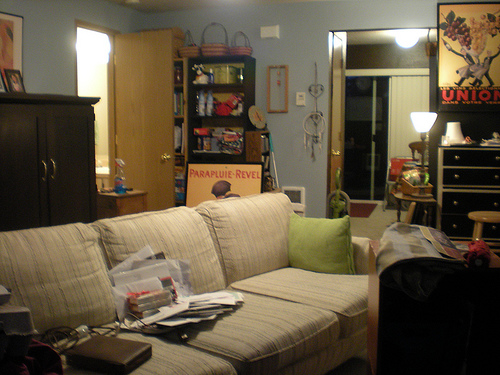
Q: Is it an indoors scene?
A: Yes, it is indoors.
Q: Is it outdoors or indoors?
A: It is indoors.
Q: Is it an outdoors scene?
A: No, it is indoors.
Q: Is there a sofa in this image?
A: Yes, there is a sofa.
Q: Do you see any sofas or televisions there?
A: Yes, there is a sofa.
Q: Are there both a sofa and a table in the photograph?
A: Yes, there are both a sofa and a table.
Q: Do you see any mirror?
A: No, there are no mirrors.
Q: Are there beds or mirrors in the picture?
A: No, there are no mirrors or beds.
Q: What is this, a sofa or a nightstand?
A: This is a sofa.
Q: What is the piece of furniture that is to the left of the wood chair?
A: The piece of furniture is a sofa.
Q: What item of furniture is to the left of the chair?
A: The piece of furniture is a sofa.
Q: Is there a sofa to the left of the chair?
A: Yes, there is a sofa to the left of the chair.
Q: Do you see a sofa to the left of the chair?
A: Yes, there is a sofa to the left of the chair.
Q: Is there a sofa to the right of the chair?
A: No, the sofa is to the left of the chair.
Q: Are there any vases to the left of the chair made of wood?
A: No, there is a sofa to the left of the chair.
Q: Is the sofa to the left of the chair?
A: Yes, the sofa is to the left of the chair.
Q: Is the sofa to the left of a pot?
A: No, the sofa is to the left of the chair.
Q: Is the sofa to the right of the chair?
A: No, the sofa is to the left of the chair.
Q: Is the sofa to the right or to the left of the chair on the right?
A: The sofa is to the left of the chair.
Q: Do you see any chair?
A: Yes, there is a chair.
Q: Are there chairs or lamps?
A: Yes, there is a chair.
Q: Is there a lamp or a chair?
A: Yes, there is a chair.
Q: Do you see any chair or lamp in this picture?
A: Yes, there is a chair.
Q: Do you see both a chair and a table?
A: Yes, there are both a chair and a table.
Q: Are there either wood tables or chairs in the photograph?
A: Yes, there is a wood chair.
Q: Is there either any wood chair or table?
A: Yes, there is a wood chair.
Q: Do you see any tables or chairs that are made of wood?
A: Yes, the chair is made of wood.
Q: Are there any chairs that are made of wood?
A: Yes, there is a chair that is made of wood.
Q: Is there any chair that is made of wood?
A: Yes, there is a chair that is made of wood.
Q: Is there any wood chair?
A: Yes, there is a chair that is made of wood.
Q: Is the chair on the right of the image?
A: Yes, the chair is on the right of the image.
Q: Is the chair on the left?
A: No, the chair is on the right of the image.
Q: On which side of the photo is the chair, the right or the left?
A: The chair is on the right of the image.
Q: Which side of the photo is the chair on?
A: The chair is on the right of the image.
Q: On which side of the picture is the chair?
A: The chair is on the right of the image.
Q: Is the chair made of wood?
A: Yes, the chair is made of wood.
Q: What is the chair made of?
A: The chair is made of wood.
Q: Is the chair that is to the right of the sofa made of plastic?
A: No, the chair is made of wood.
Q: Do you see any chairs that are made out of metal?
A: No, there is a chair but it is made of wood.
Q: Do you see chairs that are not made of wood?
A: No, there is a chair but it is made of wood.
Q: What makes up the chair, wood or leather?
A: The chair is made of wood.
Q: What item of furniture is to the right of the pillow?
A: The piece of furniture is a chair.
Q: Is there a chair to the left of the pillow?
A: No, the chair is to the right of the pillow.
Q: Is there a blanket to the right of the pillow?
A: No, there is a chair to the right of the pillow.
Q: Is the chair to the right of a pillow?
A: Yes, the chair is to the right of a pillow.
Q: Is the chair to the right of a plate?
A: No, the chair is to the right of a pillow.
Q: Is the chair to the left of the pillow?
A: No, the chair is to the right of the pillow.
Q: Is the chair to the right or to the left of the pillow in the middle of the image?
A: The chair is to the right of the pillow.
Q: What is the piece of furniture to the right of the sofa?
A: The piece of furniture is a chair.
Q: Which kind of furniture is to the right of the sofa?
A: The piece of furniture is a chair.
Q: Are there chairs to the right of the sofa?
A: Yes, there is a chair to the right of the sofa.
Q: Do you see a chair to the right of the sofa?
A: Yes, there is a chair to the right of the sofa.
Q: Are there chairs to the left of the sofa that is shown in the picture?
A: No, the chair is to the right of the sofa.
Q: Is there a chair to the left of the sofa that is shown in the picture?
A: No, the chair is to the right of the sofa.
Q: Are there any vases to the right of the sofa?
A: No, there is a chair to the right of the sofa.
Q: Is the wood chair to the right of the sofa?
A: Yes, the chair is to the right of the sofa.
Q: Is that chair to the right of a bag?
A: No, the chair is to the right of the sofa.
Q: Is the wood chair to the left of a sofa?
A: No, the chair is to the right of a sofa.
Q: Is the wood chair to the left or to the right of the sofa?
A: The chair is to the right of the sofa.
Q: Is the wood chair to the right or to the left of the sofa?
A: The chair is to the right of the sofa.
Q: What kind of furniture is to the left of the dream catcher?
A: The piece of furniture is a bookshelf.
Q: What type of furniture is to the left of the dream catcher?
A: The piece of furniture is a bookshelf.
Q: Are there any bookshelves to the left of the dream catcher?
A: Yes, there is a bookshelf to the left of the dream catcher.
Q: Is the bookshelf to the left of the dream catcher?
A: Yes, the bookshelf is to the left of the dream catcher.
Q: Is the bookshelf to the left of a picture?
A: No, the bookshelf is to the left of the dream catcher.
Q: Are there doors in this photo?
A: Yes, there is a door.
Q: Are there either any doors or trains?
A: Yes, there is a door.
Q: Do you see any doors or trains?
A: Yes, there is a door.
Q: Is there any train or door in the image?
A: Yes, there is a door.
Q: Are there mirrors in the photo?
A: No, there are no mirrors.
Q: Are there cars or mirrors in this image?
A: No, there are no mirrors or cars.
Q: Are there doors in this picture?
A: Yes, there are doors.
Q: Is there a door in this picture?
A: Yes, there are doors.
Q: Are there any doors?
A: Yes, there are doors.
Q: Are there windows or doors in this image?
A: Yes, there are doors.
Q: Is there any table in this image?
A: Yes, there is a table.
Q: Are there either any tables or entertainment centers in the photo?
A: Yes, there is a table.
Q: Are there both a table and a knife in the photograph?
A: No, there is a table but no knives.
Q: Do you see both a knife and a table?
A: No, there is a table but no knives.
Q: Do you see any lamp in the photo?
A: Yes, there is a lamp.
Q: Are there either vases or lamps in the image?
A: Yes, there is a lamp.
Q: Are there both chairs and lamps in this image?
A: Yes, there are both a lamp and a chair.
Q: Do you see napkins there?
A: No, there are no napkins.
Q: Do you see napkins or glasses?
A: No, there are no napkins or glasses.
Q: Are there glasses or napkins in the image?
A: No, there are no napkins or glasses.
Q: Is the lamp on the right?
A: Yes, the lamp is on the right of the image.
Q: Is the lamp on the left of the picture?
A: No, the lamp is on the right of the image.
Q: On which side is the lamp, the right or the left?
A: The lamp is on the right of the image.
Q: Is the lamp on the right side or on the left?
A: The lamp is on the right of the image.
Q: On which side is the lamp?
A: The lamp is on the right of the image.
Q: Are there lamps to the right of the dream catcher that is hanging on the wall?
A: Yes, there is a lamp to the right of the dream catcher.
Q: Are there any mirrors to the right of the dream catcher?
A: No, there is a lamp to the right of the dream catcher.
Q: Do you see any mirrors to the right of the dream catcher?
A: No, there is a lamp to the right of the dream catcher.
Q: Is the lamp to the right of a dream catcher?
A: Yes, the lamp is to the right of a dream catcher.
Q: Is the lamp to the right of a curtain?
A: No, the lamp is to the right of a dream catcher.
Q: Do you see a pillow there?
A: Yes, there is a pillow.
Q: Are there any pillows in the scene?
A: Yes, there is a pillow.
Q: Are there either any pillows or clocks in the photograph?
A: Yes, there is a pillow.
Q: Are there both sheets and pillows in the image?
A: No, there is a pillow but no sheets.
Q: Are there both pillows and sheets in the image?
A: No, there is a pillow but no sheets.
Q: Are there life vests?
A: No, there are no life vests.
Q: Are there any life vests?
A: No, there are no life vests.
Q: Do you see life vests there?
A: No, there are no life vests.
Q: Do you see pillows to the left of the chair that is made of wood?
A: Yes, there is a pillow to the left of the chair.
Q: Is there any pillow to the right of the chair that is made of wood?
A: No, the pillow is to the left of the chair.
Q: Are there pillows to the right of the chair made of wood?
A: No, the pillow is to the left of the chair.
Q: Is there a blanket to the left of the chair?
A: No, there is a pillow to the left of the chair.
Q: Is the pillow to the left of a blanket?
A: No, the pillow is to the left of the chair.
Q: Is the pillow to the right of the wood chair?
A: No, the pillow is to the left of the chair.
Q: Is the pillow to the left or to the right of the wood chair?
A: The pillow is to the left of the chair.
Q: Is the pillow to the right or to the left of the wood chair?
A: The pillow is to the left of the chair.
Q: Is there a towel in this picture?
A: No, there are no towels.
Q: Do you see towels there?
A: No, there are no towels.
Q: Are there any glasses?
A: No, there are no glasses.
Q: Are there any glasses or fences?
A: No, there are no glasses or fences.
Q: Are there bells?
A: No, there are no bells.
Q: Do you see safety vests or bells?
A: No, there are no bells or safety vests.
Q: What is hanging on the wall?
A: The dream catcher is hanging on the wall.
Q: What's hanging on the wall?
A: The dream catcher is hanging on the wall.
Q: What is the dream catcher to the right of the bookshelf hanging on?
A: The dream catcher is hanging on the wall.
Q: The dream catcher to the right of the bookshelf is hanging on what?
A: The dream catcher is hanging on the wall.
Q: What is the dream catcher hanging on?
A: The dream catcher is hanging on the wall.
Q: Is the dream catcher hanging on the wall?
A: Yes, the dream catcher is hanging on the wall.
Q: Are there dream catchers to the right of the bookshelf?
A: Yes, there is a dream catcher to the right of the bookshelf.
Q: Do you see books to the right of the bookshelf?
A: No, there is a dream catcher to the right of the bookshelf.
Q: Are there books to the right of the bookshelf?
A: No, there is a dream catcher to the right of the bookshelf.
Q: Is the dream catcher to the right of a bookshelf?
A: Yes, the dream catcher is to the right of a bookshelf.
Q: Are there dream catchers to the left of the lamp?
A: Yes, there is a dream catcher to the left of the lamp.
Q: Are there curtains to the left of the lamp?
A: No, there is a dream catcher to the left of the lamp.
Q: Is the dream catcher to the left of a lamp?
A: Yes, the dream catcher is to the left of a lamp.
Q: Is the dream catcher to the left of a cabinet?
A: No, the dream catcher is to the left of a lamp.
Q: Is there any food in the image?
A: No, there is no food.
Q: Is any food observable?
A: No, there is no food.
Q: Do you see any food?
A: No, there is no food.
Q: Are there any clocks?
A: No, there are no clocks.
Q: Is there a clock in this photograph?
A: No, there are no clocks.